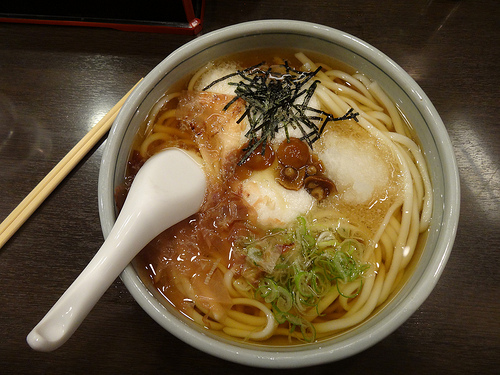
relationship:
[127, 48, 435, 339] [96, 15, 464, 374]
food in bowl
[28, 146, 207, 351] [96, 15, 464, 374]
spoon in bowl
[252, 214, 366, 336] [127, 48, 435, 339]
onions in food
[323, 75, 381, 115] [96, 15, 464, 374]
noodles in bowl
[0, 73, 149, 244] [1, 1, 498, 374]
chopsticks on table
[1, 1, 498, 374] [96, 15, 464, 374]
table under bowl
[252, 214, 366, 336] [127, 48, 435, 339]
onions on food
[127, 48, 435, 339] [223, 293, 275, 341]
food has noodles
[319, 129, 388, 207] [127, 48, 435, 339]
cream in food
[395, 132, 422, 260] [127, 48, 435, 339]
noodles in food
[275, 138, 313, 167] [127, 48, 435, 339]
mushroom top of food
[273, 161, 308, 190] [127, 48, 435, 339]
mushroom top of food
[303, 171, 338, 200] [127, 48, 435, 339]
mushroom top of food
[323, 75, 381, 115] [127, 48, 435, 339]
noodles in food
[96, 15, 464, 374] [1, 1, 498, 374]
bowl on table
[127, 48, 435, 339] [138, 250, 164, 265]
food has broth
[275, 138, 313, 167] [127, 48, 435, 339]
mushroom in soup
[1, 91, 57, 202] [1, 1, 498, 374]
reflection on table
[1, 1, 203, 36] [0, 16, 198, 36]
tray has edge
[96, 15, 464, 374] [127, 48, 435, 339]
bowl of food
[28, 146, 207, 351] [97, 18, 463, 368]
spoon has bowl